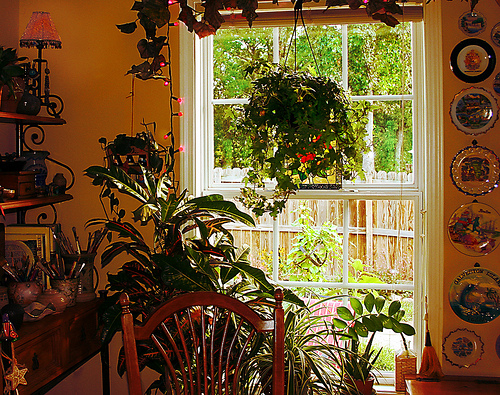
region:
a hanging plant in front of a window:
[238, 23, 380, 203]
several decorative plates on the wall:
[429, 12, 492, 354]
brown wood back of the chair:
[129, 298, 280, 394]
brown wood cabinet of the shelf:
[28, 315, 87, 368]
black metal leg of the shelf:
[93, 351, 123, 393]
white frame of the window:
[358, 185, 423, 199]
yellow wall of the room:
[74, 23, 114, 123]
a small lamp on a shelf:
[16, 10, 61, 97]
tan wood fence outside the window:
[357, 200, 400, 272]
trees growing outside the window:
[348, 26, 410, 160]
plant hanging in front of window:
[237, 13, 370, 202]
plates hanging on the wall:
[447, 12, 498, 385]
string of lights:
[149, 34, 203, 190]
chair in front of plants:
[103, 295, 313, 394]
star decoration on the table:
[7, 343, 28, 393]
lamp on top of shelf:
[14, 6, 74, 121]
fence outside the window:
[207, 161, 407, 291]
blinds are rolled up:
[197, 4, 424, 40]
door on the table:
[16, 301, 135, 388]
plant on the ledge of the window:
[323, 317, 390, 393]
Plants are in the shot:
[10, 4, 442, 394]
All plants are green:
[80, 8, 449, 393]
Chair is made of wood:
[89, 264, 307, 394]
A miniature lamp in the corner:
[16, 4, 76, 121]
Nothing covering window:
[178, 18, 433, 349]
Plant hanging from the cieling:
[246, 48, 379, 201]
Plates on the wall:
[415, 5, 499, 369]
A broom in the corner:
[410, 305, 446, 381]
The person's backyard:
[206, 128, 428, 330]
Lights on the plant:
[120, 5, 207, 200]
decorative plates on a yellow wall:
[441, 34, 498, 373]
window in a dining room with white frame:
[177, 0, 442, 393]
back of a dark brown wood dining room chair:
[115, 285, 287, 386]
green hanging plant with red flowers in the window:
[237, 0, 360, 208]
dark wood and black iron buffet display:
[0, 5, 114, 380]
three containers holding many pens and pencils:
[1, 224, 102, 316]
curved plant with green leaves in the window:
[326, 292, 418, 384]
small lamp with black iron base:
[12, 9, 64, 118]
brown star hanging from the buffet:
[1, 360, 26, 390]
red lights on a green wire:
[155, 8, 186, 194]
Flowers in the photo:
[242, 71, 356, 216]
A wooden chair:
[149, 303, 284, 389]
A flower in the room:
[97, 130, 224, 282]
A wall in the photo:
[445, 120, 485, 335]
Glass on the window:
[365, 54, 410, 173]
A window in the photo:
[211, 44, 405, 201]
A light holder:
[21, 8, 62, 123]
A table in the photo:
[43, 302, 111, 356]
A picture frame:
[3, 217, 59, 265]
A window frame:
[180, 37, 212, 239]